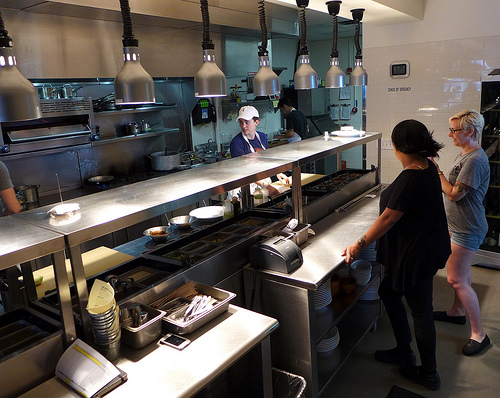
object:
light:
[114, 37, 156, 105]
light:
[193, 50, 225, 98]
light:
[253, 49, 280, 99]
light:
[293, 50, 319, 91]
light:
[324, 53, 346, 88]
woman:
[229, 105, 290, 200]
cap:
[237, 105, 260, 121]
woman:
[341, 118, 453, 391]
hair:
[391, 119, 445, 160]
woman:
[430, 108, 492, 358]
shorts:
[447, 227, 488, 251]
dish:
[188, 205, 224, 220]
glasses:
[447, 126, 466, 134]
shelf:
[0, 126, 384, 271]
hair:
[448, 109, 485, 144]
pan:
[87, 174, 114, 185]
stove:
[89, 162, 190, 186]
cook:
[273, 98, 309, 142]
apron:
[287, 131, 301, 143]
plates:
[312, 281, 330, 308]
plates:
[318, 327, 340, 350]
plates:
[358, 273, 380, 301]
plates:
[349, 260, 371, 274]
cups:
[90, 307, 125, 359]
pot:
[145, 148, 180, 170]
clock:
[389, 61, 410, 78]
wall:
[363, 1, 499, 192]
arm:
[356, 178, 416, 254]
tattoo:
[357, 234, 366, 246]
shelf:
[248, 181, 427, 389]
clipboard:
[340, 104, 350, 120]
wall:
[299, 35, 364, 168]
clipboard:
[328, 103, 338, 121]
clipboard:
[338, 83, 351, 100]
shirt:
[442, 146, 491, 237]